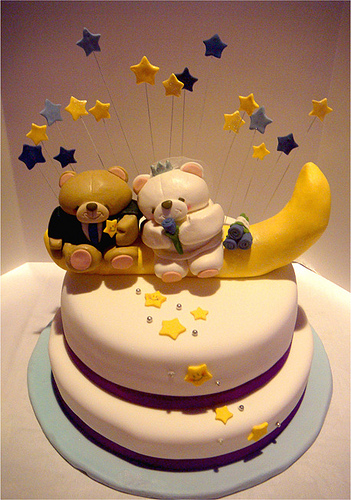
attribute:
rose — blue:
[160, 215, 176, 232]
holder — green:
[158, 225, 186, 254]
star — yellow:
[122, 54, 162, 86]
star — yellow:
[301, 92, 334, 125]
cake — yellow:
[26, 151, 349, 478]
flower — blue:
[228, 222, 244, 239]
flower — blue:
[234, 231, 254, 251]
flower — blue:
[221, 173, 324, 251]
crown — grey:
[149, 158, 172, 176]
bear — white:
[135, 156, 231, 283]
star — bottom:
[192, 25, 226, 67]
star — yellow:
[254, 143, 273, 162]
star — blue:
[310, 100, 333, 119]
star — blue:
[274, 133, 299, 153]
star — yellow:
[221, 111, 244, 132]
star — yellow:
[203, 36, 227, 58]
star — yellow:
[131, 55, 158, 84]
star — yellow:
[184, 364, 212, 389]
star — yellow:
[220, 111, 244, 136]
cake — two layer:
[16, 27, 334, 497]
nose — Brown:
[80, 207, 104, 221]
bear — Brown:
[46, 167, 152, 287]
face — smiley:
[183, 363, 213, 387]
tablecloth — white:
[3, 259, 348, 498]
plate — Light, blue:
[26, 331, 344, 491]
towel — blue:
[223, 217, 247, 241]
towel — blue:
[235, 233, 255, 250]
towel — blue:
[221, 235, 237, 252]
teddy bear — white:
[131, 161, 228, 281]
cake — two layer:
[46, 264, 315, 472]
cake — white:
[39, 215, 326, 472]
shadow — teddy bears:
[71, 278, 231, 300]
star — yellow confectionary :
[131, 282, 269, 447]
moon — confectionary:
[43, 163, 332, 280]